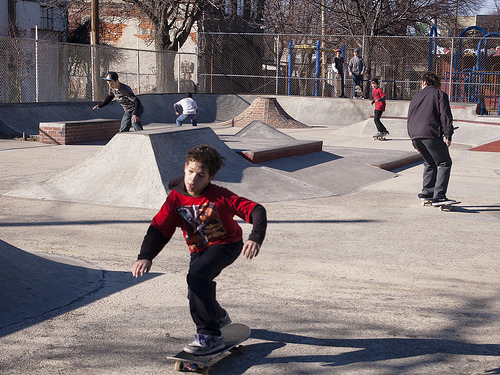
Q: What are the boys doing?
A: Skateboarding.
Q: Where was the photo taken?
A: Skate park.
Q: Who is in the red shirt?
A: Two boys skateboarding.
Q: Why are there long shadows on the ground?
A: It is afternoon.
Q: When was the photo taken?
A: Later in the day.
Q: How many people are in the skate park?
A: Seven.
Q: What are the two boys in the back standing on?
A: A skate ramp.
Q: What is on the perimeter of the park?
A: Chain link fence.